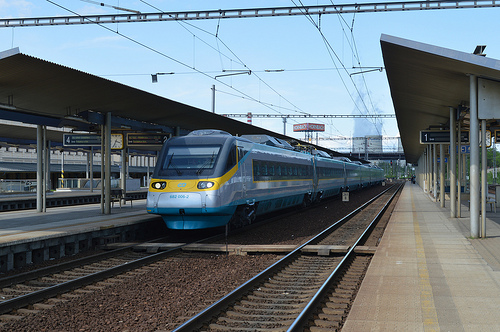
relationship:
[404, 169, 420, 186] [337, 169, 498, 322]
people waiting on platform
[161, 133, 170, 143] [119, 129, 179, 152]
number on sign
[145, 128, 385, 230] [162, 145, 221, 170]
train has window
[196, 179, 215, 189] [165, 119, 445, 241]
headlight on train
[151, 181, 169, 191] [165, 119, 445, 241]
headlight on train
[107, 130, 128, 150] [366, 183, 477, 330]
clock between platform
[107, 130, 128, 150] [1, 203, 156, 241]
clock between platform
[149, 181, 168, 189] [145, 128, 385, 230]
headlight on train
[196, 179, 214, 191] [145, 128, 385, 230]
headlight on train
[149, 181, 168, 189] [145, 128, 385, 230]
headlight of a train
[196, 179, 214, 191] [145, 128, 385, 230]
headlight of a train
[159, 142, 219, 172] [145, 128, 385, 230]
window of a train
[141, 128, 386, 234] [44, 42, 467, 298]
train in station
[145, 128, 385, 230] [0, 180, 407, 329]
train on tracks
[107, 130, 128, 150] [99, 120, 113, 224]
clock on column